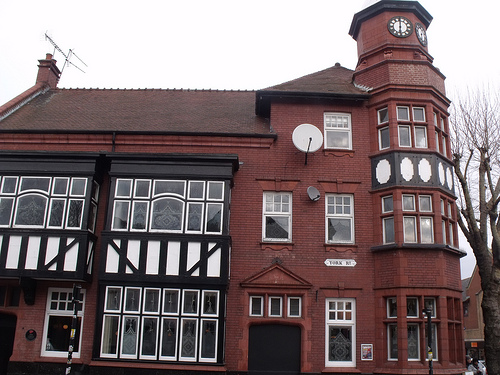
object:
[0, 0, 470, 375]
building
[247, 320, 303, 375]
door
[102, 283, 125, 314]
windows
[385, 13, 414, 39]
clock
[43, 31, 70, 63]
antennas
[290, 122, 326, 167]
satellite dish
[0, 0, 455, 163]
top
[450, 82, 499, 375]
tree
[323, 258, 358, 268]
sign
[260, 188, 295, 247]
windows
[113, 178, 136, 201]
windows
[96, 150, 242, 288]
window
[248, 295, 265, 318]
windows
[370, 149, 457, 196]
design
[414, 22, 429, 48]
clocks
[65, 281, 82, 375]
light pole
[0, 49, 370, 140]
roof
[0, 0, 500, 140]
sky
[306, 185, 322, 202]
satellite dish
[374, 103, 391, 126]
windows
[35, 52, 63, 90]
chimney